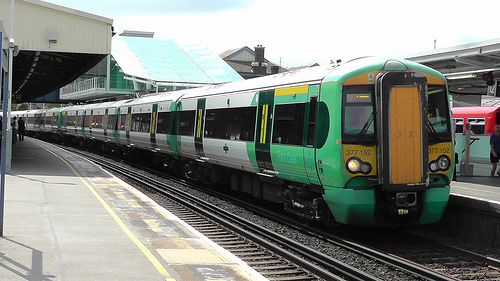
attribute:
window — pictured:
[342, 80, 376, 146]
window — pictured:
[424, 77, 451, 142]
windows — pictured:
[454, 117, 485, 132]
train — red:
[452, 102, 499, 185]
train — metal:
[7, 89, 459, 231]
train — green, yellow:
[13, 57, 455, 237]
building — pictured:
[223, 40, 285, 87]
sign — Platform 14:
[9, 90, 29, 104]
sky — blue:
[97, 0, 476, 62]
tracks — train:
[219, 222, 491, 278]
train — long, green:
[12, 82, 477, 228]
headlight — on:
[341, 156, 375, 176]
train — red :
[449, 103, 499, 163]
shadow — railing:
[18, 245, 54, 277]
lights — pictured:
[345, 155, 371, 175]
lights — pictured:
[428, 152, 449, 170]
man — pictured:
[489, 121, 499, 183]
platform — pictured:
[1, 138, 267, 280]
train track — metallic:
[61, 141, 499, 279]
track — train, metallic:
[62, 137, 498, 278]